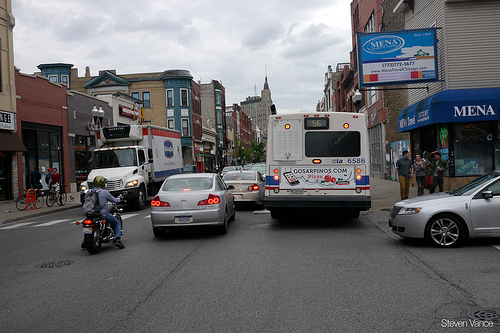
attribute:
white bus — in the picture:
[263, 112, 371, 223]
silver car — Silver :
[150, 173, 236, 239]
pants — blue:
[104, 209, 123, 242]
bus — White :
[259, 109, 375, 229]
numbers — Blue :
[346, 155, 366, 165]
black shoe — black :
[113, 237, 125, 249]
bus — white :
[212, 80, 492, 290]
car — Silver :
[148, 172, 235, 234]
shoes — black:
[79, 225, 129, 255]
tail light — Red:
[76, 220, 102, 226]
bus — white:
[258, 104, 378, 239]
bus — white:
[207, 107, 371, 222]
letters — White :
[442, 102, 498, 120]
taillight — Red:
[84, 221, 94, 229]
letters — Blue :
[276, 157, 366, 197]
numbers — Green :
[304, 113, 329, 134]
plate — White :
[169, 215, 195, 232]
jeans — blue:
[103, 207, 124, 241]